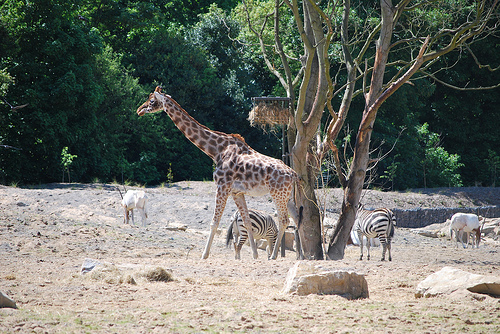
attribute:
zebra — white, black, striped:
[222, 204, 279, 254]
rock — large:
[280, 256, 370, 302]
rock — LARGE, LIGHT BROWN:
[275, 253, 377, 297]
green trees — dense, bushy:
[0, 1, 288, 185]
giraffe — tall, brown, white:
[134, 83, 321, 260]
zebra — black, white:
[355, 205, 397, 261]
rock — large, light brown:
[412, 262, 498, 304]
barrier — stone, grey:
[382, 202, 499, 228]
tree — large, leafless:
[288, 24, 455, 236]